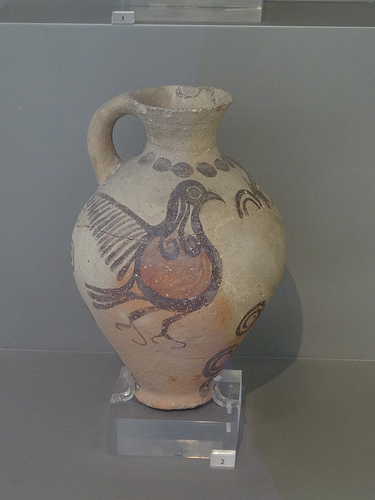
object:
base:
[106, 366, 242, 468]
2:
[221, 458, 225, 464]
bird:
[84, 179, 227, 349]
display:
[0, 0, 375, 500]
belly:
[135, 231, 223, 311]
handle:
[87, 91, 145, 190]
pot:
[70, 85, 287, 410]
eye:
[186, 185, 202, 199]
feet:
[114, 323, 186, 350]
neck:
[139, 113, 224, 157]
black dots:
[137, 152, 236, 179]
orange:
[98, 229, 242, 411]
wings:
[86, 192, 152, 281]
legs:
[129, 305, 193, 334]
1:
[122, 16, 125, 21]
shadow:
[223, 265, 303, 462]